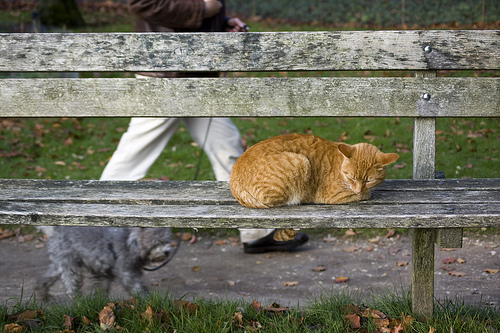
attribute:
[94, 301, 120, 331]
leaf — dead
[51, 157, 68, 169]
leaf — unraked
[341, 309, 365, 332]
leaf — dead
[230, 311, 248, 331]
leaf — dead, unraked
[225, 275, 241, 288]
leaf — dead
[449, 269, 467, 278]
leaf — dead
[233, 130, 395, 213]
cat — tiger, orange tabby, orange, sleeping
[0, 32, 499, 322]
ground — gray, wooden, leaf covered, grassy, green, brown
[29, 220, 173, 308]
dog — small, grey, silver, furry, being walked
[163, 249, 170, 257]
nose — black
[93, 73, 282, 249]
pants — white, khaki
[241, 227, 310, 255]
sandal — dark, being worn, black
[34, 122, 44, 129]
leaf — dead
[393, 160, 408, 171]
leaf — dead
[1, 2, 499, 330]
park — in autumn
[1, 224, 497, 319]
sidewalk — walked with traffic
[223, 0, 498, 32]
shrub — green